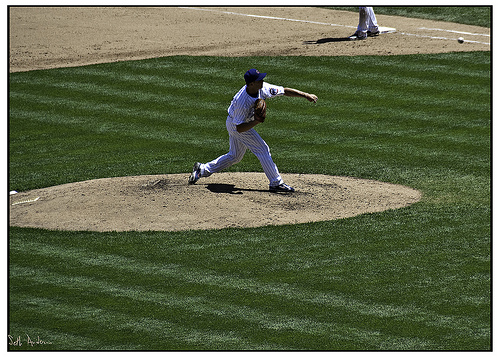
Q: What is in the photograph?
A: A baseball field.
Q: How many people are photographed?
A: Two.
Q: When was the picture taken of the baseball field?
A: Daytime.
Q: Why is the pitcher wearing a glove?
A: To catch balls.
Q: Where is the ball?
A: In air.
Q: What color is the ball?
A: White.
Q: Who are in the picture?
A: Baseball players.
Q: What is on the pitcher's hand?
A: A baseball glove.